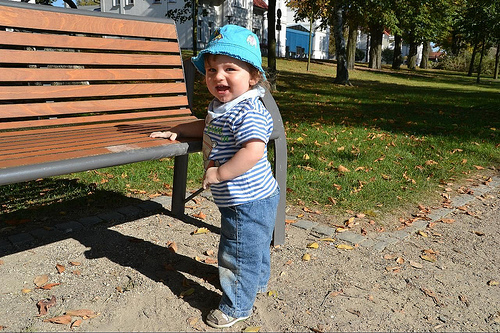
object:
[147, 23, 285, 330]
child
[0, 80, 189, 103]
wood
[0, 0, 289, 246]
metal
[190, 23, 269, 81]
child's hat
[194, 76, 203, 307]
shoe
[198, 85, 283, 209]
shirt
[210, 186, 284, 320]
jeans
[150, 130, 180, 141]
hand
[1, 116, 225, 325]
shadow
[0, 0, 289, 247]
bench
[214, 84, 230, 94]
smile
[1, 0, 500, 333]
park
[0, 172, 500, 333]
sidewalk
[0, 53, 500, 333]
ground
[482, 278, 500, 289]
leaves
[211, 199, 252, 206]
stripes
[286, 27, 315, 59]
blue door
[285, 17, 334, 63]
building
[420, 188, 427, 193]
grass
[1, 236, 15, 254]
bricks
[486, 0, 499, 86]
trees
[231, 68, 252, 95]
skin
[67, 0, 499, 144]
background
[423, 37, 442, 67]
buildings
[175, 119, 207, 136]
right arm